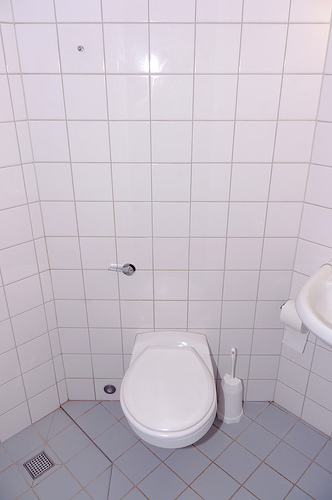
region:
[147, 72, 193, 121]
square white ceramic tile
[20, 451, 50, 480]
square drain in floor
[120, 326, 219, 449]
toilet attached to wall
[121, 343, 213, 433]
top of closed cover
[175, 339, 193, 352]
light reflection on porcelain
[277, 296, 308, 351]
roll of white toilet paper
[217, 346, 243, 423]
toilet brush in holder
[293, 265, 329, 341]
curved edge of seat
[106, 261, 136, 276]
metal handle on wall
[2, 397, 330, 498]
light blue floor tiles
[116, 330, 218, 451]
clean white porcelain toilet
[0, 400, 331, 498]
white tile floor with yellowed grout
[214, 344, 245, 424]
white toilet brush case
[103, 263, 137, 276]
chrome toilet lever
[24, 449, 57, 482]
silver drain in tile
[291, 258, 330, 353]
white porcelain sink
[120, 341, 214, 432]
white toilet lid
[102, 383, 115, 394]
chrome capped pipe in wall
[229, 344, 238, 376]
toilet brush handle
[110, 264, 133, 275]
grey metal toilet handle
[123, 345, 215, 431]
white plastic toilet seat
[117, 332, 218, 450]
white ceramic toilet bowl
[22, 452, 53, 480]
water drain on floor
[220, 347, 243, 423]
white plastic toilet cleaner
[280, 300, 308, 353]
toilet paper on wall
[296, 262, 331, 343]
white ceramic bathroom sink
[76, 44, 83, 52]
hole in bathroom wall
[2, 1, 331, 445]
white tiles on wall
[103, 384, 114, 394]
metal cap on wall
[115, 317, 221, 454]
a toilet with the lid down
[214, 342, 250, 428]
a white toilet brush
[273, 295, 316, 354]
a roll of toilet paper on the wall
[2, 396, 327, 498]
grey tiles for the bathroom floor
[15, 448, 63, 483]
a drain in the floor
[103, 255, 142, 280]
the flusher for the toilet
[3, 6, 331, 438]
white tiles for the bathroom wall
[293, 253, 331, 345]
a white sink on the wall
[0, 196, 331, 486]
a white and grey bathroom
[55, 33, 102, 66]
a black spot on one of the white tiles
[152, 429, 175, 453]
edge of a toilet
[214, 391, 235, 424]
part of a shade